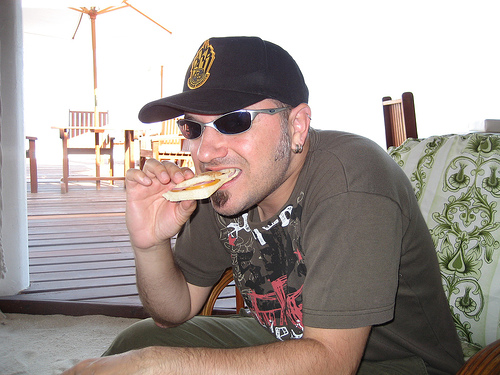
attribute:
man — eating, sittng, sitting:
[60, 38, 465, 374]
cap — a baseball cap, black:
[137, 36, 310, 124]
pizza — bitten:
[166, 169, 240, 202]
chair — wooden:
[51, 106, 116, 192]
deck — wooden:
[5, 177, 259, 313]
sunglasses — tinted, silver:
[178, 108, 278, 139]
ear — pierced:
[290, 104, 312, 154]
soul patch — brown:
[212, 191, 229, 208]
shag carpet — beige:
[0, 313, 143, 374]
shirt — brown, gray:
[176, 128, 466, 371]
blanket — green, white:
[387, 133, 499, 365]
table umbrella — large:
[68, 3, 175, 140]